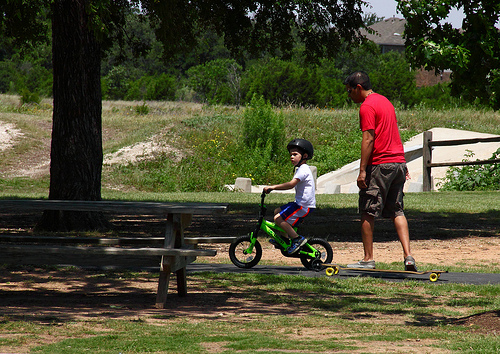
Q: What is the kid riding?
A: A bike.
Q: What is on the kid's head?
A: A helmet.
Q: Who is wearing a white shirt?
A: The little boy.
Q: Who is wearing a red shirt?
A: The man.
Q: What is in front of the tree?
A: A bench.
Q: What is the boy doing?
A: Riding a bike.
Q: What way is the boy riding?
A: Left.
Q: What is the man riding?
A: A skateboard.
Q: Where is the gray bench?
A: On the left.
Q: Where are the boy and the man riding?
A: On asphalt.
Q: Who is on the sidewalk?
A: The boy and the man.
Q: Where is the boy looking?
A: To the left.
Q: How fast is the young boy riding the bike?
A: Slowly.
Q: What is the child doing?
A: Riding a bicycle.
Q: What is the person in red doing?
A: Watching the child.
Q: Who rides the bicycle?
A: A child.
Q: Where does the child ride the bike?
A: In a park.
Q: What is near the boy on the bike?
A: A picnic table.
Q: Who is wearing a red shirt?
A: The man.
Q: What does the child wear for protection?
A: A helmet.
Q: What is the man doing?
A: Riding a skateboard.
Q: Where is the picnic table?
A: In the park.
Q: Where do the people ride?
A: On a paved bicycle path.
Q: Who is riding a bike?
A: A boy.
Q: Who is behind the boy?
A: A man.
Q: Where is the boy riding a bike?
A: In the park.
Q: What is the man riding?
A: A skateboard.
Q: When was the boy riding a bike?
A: During daylight hours.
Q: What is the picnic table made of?
A: Wood.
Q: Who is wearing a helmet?
A: The boy.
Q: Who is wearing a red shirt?
A: The man.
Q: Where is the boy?
A: On a bike.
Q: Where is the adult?
A: Behind the bike.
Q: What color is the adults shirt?
A: Red.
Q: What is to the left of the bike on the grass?
A: A bench.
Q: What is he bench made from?
A: Wood.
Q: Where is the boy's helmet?
A: On his head.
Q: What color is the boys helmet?
A: Black.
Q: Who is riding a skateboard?
A: The adult.